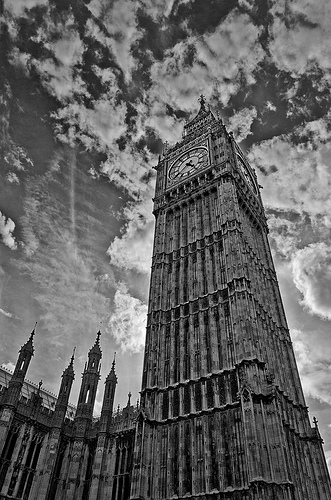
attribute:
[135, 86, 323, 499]
tower — tside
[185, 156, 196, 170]
hands — black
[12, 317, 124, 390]
tops — steep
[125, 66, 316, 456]
tower — big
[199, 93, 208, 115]
spire — pointy 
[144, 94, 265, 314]
gothic tower — tall gothic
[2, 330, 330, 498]
building — main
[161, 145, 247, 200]
clock — showing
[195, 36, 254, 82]
cloud — bright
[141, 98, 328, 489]
tower — tall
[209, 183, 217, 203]
arch — gothic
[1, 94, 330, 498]
building — large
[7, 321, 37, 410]
spire — gothic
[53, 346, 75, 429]
spire — gothic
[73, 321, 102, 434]
spire — gothic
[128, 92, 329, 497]
building — tall, turret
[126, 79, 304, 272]
building — very large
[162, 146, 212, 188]
clock — tower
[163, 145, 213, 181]
clock — large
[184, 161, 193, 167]
hour hand — large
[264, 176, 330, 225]
clouds — white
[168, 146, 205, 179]
numerals — roman